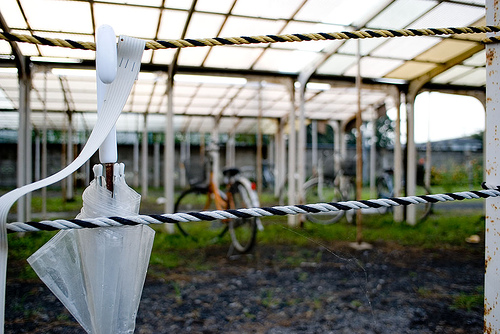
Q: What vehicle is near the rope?
A: A bicycle.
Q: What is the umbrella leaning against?
A: Ropes.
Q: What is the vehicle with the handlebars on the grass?
A: A bicycle.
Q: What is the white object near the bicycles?
A: An umbrella.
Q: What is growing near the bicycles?
A: Grass.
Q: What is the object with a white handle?
A: An umbrella.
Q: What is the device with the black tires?
A: A bicycle.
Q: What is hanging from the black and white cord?
A: Umbrella.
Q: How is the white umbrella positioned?
A: Hanging.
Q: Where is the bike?
A: Background.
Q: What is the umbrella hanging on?
A: Rope.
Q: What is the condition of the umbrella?
A: Closed.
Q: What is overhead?
A: Skylight.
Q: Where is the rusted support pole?
A: Right.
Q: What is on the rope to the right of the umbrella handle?
A: White strap.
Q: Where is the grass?
A: Under bikes.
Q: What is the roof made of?
A: Corrugated plastic.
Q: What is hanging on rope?
A: Umbrella.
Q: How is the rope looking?
A: White.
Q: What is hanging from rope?
A: Plastic.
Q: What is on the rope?
A: Umbrella.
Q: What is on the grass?
A: Bike.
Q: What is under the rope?
A: A spider web.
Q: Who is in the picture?
A: No people.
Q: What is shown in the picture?
A: A covered grassy spot.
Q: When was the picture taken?
A: Daytime.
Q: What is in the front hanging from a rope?
A: An umbrella.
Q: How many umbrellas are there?
A: One.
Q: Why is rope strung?
A: As a barrier.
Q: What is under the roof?
A: Bikes.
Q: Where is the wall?
A: Behind the poles.